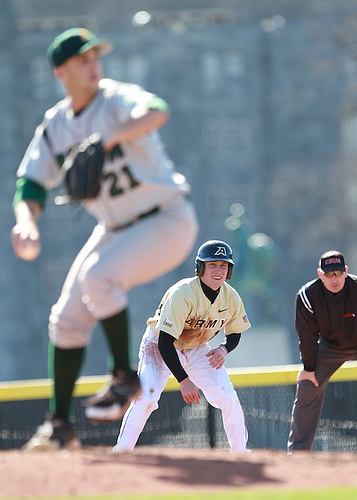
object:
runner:
[110, 238, 252, 458]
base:
[156, 429, 228, 469]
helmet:
[45, 26, 113, 77]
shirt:
[146, 275, 251, 351]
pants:
[48, 191, 200, 350]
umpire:
[286, 249, 357, 451]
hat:
[318, 250, 346, 275]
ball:
[130, 10, 150, 26]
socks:
[46, 337, 88, 422]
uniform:
[128, 273, 252, 383]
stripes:
[301, 285, 313, 310]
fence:
[0, 359, 357, 452]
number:
[104, 171, 125, 199]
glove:
[60, 131, 107, 200]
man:
[9, 26, 199, 457]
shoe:
[19, 410, 83, 459]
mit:
[54, 157, 132, 206]